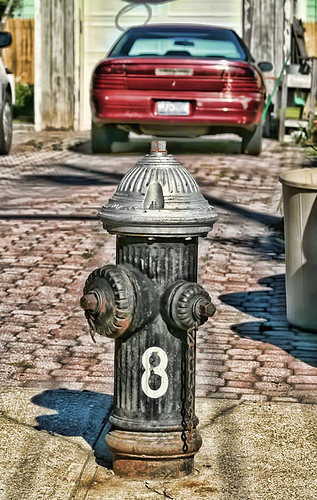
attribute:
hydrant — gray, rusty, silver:
[80, 141, 219, 480]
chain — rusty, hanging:
[187, 326, 197, 446]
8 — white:
[140, 347, 169, 398]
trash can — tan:
[277, 167, 316, 334]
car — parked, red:
[90, 22, 271, 157]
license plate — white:
[156, 101, 190, 117]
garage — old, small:
[32, 0, 291, 133]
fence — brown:
[0, 20, 316, 85]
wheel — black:
[242, 122, 263, 156]